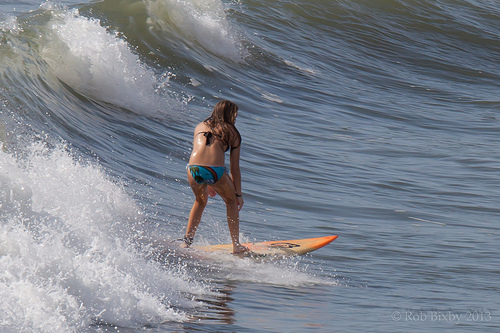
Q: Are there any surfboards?
A: Yes, there is a surfboard.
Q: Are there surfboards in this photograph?
A: Yes, there is a surfboard.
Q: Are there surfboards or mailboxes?
A: Yes, there is a surfboard.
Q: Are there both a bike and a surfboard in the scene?
A: No, there is a surfboard but no bikes.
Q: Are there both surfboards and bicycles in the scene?
A: No, there is a surfboard but no bikes.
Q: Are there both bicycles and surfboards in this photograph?
A: No, there is a surfboard but no bikes.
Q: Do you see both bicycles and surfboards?
A: No, there is a surfboard but no bikes.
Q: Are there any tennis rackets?
A: No, there are no tennis rackets.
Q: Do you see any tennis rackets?
A: No, there are no tennis rackets.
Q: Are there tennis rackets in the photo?
A: No, there are no tennis rackets.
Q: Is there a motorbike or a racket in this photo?
A: No, there are no rackets or motorcycles.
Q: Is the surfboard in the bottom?
A: Yes, the surfboard is in the bottom of the image.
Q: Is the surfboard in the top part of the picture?
A: No, the surfboard is in the bottom of the image.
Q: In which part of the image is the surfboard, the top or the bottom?
A: The surfboard is in the bottom of the image.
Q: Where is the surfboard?
A: The surfboard is in the water.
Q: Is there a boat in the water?
A: No, there is a surfboard in the water.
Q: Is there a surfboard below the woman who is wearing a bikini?
A: Yes, there is a surfboard below the woman.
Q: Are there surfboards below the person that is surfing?
A: Yes, there is a surfboard below the woman.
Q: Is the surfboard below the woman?
A: Yes, the surfboard is below the woman.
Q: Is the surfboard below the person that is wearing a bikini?
A: Yes, the surfboard is below the woman.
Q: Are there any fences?
A: No, there are no fences.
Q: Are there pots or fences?
A: No, there are no fences or pots.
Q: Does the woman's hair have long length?
A: Yes, the hair is long.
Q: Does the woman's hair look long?
A: Yes, the hair is long.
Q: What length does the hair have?
A: The hair has long length.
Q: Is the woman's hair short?
A: No, the hair is long.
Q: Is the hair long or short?
A: The hair is long.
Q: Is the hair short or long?
A: The hair is long.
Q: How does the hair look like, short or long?
A: The hair is long.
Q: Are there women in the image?
A: Yes, there is a woman.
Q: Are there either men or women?
A: Yes, there is a woman.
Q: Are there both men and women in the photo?
A: No, there is a woman but no men.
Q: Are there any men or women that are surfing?
A: Yes, the woman is surfing.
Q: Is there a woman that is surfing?
A: Yes, there is a woman that is surfing.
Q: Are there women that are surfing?
A: Yes, there is a woman that is surfing.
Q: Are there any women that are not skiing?
A: Yes, there is a woman that is surfing.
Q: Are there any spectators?
A: No, there are no spectators.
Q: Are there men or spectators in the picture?
A: No, there are no spectators or men.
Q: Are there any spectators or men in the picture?
A: No, there are no spectators or men.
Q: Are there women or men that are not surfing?
A: No, there is a woman but she is surfing.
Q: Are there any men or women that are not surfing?
A: No, there is a woman but she is surfing.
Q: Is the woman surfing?
A: Yes, the woman is surfing.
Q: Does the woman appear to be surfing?
A: Yes, the woman is surfing.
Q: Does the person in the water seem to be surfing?
A: Yes, the woman is surfing.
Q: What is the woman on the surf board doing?
A: The woman is surfing.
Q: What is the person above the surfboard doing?
A: The woman is surfing.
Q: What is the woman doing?
A: The woman is surfing.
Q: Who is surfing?
A: The woman is surfing.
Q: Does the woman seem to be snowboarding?
A: No, the woman is surfing.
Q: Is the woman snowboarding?
A: No, the woman is surfing.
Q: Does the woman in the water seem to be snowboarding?
A: No, the woman is surfing.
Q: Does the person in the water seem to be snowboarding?
A: No, the woman is surfing.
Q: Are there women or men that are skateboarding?
A: No, there is a woman but she is surfing.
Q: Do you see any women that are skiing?
A: No, there is a woman but she is surfing.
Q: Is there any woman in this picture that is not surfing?
A: No, there is a woman but she is surfing.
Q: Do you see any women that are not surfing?
A: No, there is a woman but she is surfing.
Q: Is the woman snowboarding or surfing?
A: The woman is surfing.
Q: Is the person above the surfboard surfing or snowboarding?
A: The woman is surfing.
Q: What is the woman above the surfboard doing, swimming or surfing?
A: The woman is surfing.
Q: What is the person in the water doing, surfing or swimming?
A: The woman is surfing.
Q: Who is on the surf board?
A: The woman is on the surf board.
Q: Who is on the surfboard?
A: The woman is on the surf board.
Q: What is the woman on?
A: The woman is on the surfboard.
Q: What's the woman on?
A: The woman is on the surfboard.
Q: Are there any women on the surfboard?
A: Yes, there is a woman on the surfboard.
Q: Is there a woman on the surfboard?
A: Yes, there is a woman on the surfboard.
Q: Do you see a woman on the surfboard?
A: Yes, there is a woman on the surfboard.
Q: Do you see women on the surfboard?
A: Yes, there is a woman on the surfboard.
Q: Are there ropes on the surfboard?
A: No, there is a woman on the surfboard.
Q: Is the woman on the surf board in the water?
A: Yes, the woman is on the surf board.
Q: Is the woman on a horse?
A: No, the woman is on the surf board.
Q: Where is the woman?
A: The woman is in the water.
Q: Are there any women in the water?
A: Yes, there is a woman in the water.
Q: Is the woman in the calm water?
A: Yes, the woman is in the water.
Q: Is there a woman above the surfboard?
A: Yes, there is a woman above the surfboard.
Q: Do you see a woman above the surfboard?
A: Yes, there is a woman above the surfboard.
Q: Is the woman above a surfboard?
A: Yes, the woman is above a surfboard.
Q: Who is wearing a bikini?
A: The woman is wearing a bikini.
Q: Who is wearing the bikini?
A: The woman is wearing a bikini.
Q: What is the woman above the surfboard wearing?
A: The woman is wearing a bikini.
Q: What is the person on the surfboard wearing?
A: The woman is wearing a bikini.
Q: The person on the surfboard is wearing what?
A: The woman is wearing a bikini.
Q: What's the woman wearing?
A: The woman is wearing a bikini.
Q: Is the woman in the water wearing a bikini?
A: Yes, the woman is wearing a bikini.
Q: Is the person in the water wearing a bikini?
A: Yes, the woman is wearing a bikini.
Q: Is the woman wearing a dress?
A: No, the woman is wearing a bikini.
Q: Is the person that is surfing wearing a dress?
A: No, the woman is wearing a bikini.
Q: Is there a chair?
A: No, there are no chairs.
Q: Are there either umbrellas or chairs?
A: No, there are no chairs or umbrellas.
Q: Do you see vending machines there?
A: No, there are no vending machines.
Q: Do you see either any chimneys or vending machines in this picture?
A: No, there are no vending machines or chimneys.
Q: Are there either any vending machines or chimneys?
A: No, there are no vending machines or chimneys.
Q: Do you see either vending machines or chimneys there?
A: No, there are no vending machines or chimneys.